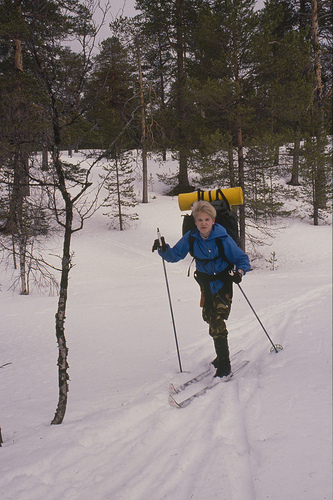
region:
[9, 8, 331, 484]
a scene outside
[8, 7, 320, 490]
a scene during the day time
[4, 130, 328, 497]
snow on the ground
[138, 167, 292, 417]
a skier with a backpack on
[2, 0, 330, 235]
some trees in the background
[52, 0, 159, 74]
a dark sky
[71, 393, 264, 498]
tracks on the ground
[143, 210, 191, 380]
a ski pole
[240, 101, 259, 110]
a piece of the tree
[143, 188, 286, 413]
A person cross-country skiing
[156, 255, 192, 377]
A metal ski pole sticking into the snow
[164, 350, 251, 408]
Two skis moving through the snow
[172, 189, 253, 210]
A yellow item rolled up and tied onto a backpack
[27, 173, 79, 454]
A small thin tree trunk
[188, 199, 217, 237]
A blond haired person looking at the camera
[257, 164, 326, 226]
Some trees in the snow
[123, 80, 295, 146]
A series of trees in the background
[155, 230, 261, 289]
A blue jacket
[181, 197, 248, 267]
A large black backpack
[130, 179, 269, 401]
this is a woman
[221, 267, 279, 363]
this is a ski pole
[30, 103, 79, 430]
this is a tree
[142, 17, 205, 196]
this is a tree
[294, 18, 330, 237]
this is a tree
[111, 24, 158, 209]
this is a tree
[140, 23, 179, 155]
this is a tree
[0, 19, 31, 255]
this is a tree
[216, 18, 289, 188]
this is a tree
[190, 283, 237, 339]
woman wearing fatigue pants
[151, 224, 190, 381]
woman holding a ski pole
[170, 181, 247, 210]
woman with a sleeping bag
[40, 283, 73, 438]
tree in the snow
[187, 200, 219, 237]
woman with blond hair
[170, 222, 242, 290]
woman wearing a blue jacket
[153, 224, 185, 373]
ski pole in the hand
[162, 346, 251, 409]
skis on the snow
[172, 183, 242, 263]
back pack on the woman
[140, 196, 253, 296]
blue jacket on the woman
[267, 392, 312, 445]
the snow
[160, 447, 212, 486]
the snow is white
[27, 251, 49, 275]
tree branches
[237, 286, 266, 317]
skiis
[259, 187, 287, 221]
tree branches of the tree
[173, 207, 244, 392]
a women standing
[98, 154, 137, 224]
a small tree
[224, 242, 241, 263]
a blue sweater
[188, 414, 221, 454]
the snow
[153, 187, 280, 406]
a person wearing a backpack